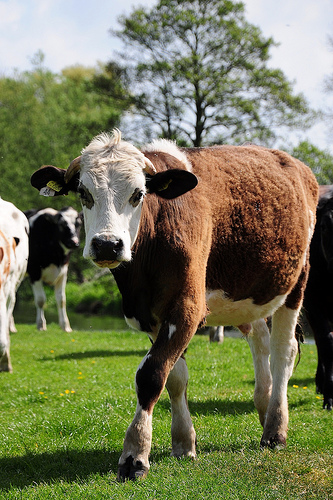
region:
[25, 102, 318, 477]
brown and white cow in a field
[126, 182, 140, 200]
eye on the cow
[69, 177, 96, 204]
eye on the cow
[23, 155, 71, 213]
ear on the cow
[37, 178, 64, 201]
tags on the cows ear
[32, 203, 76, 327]
black and white cow in a field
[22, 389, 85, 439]
grass on the ground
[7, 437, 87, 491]
shadow on the ground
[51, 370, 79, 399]
yellow flower in the grass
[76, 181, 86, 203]
eye on the cow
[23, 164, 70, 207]
cow with yellow tag on ear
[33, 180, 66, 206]
cow with white tag on ear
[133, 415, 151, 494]
cow with white lower leg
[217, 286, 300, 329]
cow has brown and white belly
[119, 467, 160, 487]
cow has black hoof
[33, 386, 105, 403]
yellow flowers in field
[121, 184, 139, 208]
cow has brown ring around its eye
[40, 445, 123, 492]
shadow on green grass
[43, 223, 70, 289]
black and white cow in distance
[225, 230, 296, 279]
cow has soft furry brown belly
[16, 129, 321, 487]
the animal is facing forwards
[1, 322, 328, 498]
grass under the animals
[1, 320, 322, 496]
the grass is kept short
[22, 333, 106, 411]
dandelions in the field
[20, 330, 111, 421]
the dandelions are yellow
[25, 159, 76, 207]
tags on the animal's ear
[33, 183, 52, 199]
this tag is white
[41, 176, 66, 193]
this tag is yellow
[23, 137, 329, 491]
this animal is brown and white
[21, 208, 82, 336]
this cow is black and white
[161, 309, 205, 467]
Leg of a cow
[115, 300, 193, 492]
Leg of a cow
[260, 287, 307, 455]
Leg of a cow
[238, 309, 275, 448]
Leg of a cow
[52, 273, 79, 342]
Leg of a cow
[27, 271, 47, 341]
Leg of a cow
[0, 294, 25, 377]
Leg of a cow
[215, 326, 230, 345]
Leg of a cow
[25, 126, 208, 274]
Head of a cow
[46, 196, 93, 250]
Head of a cow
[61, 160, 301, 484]
cow in grassy pasture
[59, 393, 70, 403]
yellow flower in field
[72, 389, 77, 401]
yellow flower in field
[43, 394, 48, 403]
yellow flower in field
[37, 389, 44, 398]
yellow flower in field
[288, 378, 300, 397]
yellow flower in field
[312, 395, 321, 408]
yellow flower in field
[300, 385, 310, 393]
yellow flower in field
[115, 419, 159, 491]
leg of the cow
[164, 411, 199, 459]
leg of the cow